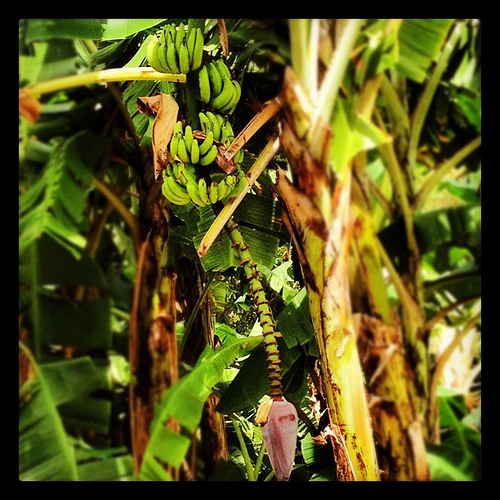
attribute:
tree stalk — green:
[282, 120, 380, 482]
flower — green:
[259, 401, 301, 481]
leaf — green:
[136, 323, 270, 483]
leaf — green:
[21, 336, 134, 482]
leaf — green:
[17, 132, 129, 364]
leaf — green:
[393, 12, 482, 176]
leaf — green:
[425, 391, 482, 485]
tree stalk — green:
[125, 156, 181, 475]